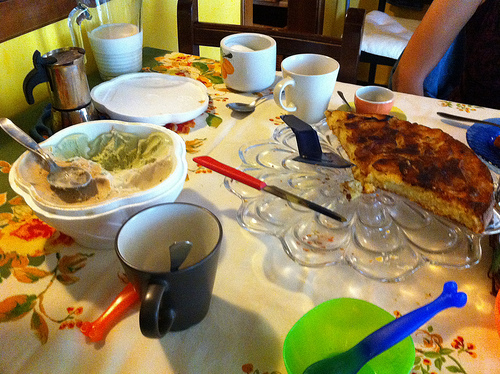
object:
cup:
[115, 200, 225, 342]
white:
[115, 201, 224, 274]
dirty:
[266, 182, 347, 227]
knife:
[192, 155, 348, 226]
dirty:
[45, 162, 93, 191]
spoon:
[0, 116, 93, 190]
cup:
[272, 53, 340, 126]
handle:
[273, 76, 297, 117]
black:
[281, 114, 356, 169]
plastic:
[92, 70, 211, 125]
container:
[6, 117, 188, 252]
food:
[18, 125, 177, 213]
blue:
[300, 280, 468, 371]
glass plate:
[224, 117, 499, 287]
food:
[322, 108, 497, 236]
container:
[21, 46, 99, 137]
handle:
[21, 50, 58, 104]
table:
[2, 44, 499, 373]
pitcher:
[67, 0, 144, 82]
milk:
[87, 22, 144, 82]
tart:
[490, 132, 499, 161]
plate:
[465, 116, 499, 172]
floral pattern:
[1, 45, 499, 374]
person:
[387, 0, 498, 110]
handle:
[168, 241, 194, 273]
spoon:
[167, 239, 193, 273]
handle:
[192, 155, 268, 195]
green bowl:
[282, 297, 417, 373]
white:
[218, 31, 278, 90]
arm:
[390, 0, 485, 106]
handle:
[436, 110, 499, 132]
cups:
[218, 30, 277, 93]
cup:
[354, 83, 396, 117]